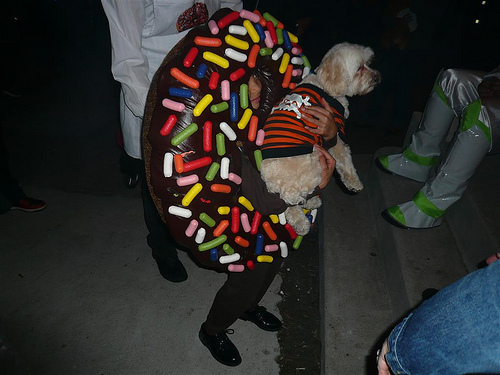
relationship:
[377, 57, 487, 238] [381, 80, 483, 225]
person wearing plastic footwear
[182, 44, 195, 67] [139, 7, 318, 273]
confection on costume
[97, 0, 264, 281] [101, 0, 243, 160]
person in apron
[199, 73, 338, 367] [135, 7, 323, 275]
boy in costume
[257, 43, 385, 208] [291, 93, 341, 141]
dog being held in hand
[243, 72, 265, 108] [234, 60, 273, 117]
face in hole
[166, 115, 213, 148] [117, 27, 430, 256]
sprinkle on costume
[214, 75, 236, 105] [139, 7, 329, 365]
sprinkle on costume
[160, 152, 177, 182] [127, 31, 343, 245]
sprinkle on costume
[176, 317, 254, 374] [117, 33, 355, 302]
shoe on boy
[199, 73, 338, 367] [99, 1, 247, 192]
boy next to person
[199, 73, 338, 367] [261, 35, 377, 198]
boy holding dog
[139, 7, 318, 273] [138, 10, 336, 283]
costume looking donut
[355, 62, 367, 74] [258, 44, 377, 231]
eye of dog